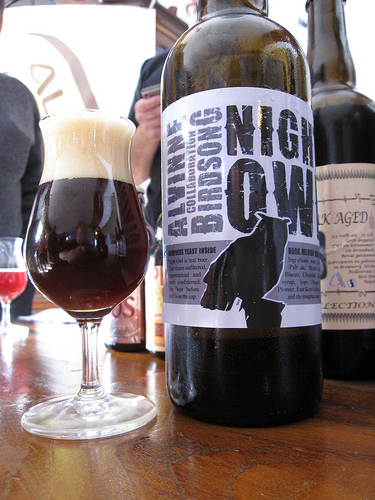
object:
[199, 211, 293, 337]
owl design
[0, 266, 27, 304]
liquid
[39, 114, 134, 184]
whitehead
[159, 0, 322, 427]
beer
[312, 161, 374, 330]
label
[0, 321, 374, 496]
table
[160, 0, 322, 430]
bottle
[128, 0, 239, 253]
person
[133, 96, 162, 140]
hand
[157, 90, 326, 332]
label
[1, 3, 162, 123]
banner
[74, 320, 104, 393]
handle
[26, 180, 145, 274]
reflection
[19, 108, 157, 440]
cup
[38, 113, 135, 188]
foam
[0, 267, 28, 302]
drink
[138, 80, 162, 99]
cellphone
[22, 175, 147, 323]
beer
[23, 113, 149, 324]
drink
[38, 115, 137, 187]
head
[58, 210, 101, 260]
man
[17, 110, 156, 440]
glass